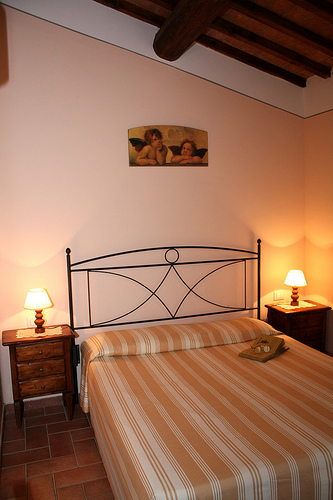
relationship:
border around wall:
[12, 1, 332, 116] [2, 0, 331, 324]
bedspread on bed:
[76, 318, 330, 500] [63, 236, 331, 498]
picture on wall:
[126, 123, 207, 168] [18, 46, 308, 269]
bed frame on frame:
[63, 236, 262, 416] [59, 233, 265, 346]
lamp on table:
[283, 264, 305, 306] [264, 296, 331, 356]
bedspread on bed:
[67, 338, 332, 472] [63, 236, 331, 498]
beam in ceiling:
[145, 5, 218, 62] [7, 2, 332, 86]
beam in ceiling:
[142, 5, 311, 81] [7, 2, 332, 86]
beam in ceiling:
[142, 5, 329, 88] [7, 2, 332, 86]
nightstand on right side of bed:
[260, 266, 332, 348] [63, 236, 331, 498]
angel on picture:
[168, 139, 207, 164] [126, 124, 208, 168]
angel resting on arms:
[168, 139, 207, 164] [170, 154, 203, 165]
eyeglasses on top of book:
[252, 336, 270, 354] [236, 333, 290, 363]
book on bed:
[238, 334, 288, 363] [103, 305, 327, 498]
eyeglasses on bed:
[252, 336, 270, 354] [103, 305, 327, 498]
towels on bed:
[236, 330, 289, 364] [75, 314, 331, 498]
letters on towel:
[258, 337, 270, 342] [239, 327, 293, 365]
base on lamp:
[33, 309, 45, 332] [24, 284, 54, 333]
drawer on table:
[14, 341, 65, 360] [3, 325, 80, 426]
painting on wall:
[128, 122, 208, 166] [0, 1, 308, 405]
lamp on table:
[22, 283, 54, 335] [3, 325, 80, 426]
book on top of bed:
[239, 331, 288, 361] [57, 301, 331, 487]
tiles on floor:
[0, 391, 116, 498] [0, 388, 116, 496]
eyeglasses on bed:
[254, 333, 276, 360] [63, 236, 331, 498]